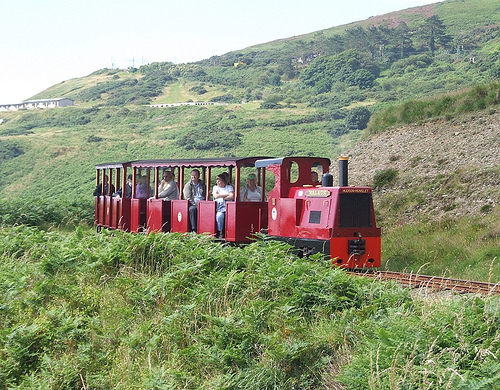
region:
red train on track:
[89, 136, 390, 262]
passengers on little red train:
[87, 144, 373, 271]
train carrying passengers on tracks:
[75, 147, 384, 265]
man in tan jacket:
[177, 167, 202, 213]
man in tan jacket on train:
[184, 170, 206, 205]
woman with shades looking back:
[209, 173, 233, 220]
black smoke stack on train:
[329, 156, 353, 181]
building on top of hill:
[2, 96, 72, 116]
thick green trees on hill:
[256, 17, 498, 124]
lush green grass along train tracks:
[11, 226, 480, 388]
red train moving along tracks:
[85, 154, 398, 286]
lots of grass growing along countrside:
[59, 275, 306, 382]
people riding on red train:
[83, 149, 394, 265]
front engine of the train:
[253, 154, 390, 276]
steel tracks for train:
[365, 258, 490, 313]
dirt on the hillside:
[377, 111, 481, 201]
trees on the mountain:
[263, 38, 418, 98]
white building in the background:
[0, 82, 83, 114]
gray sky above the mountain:
[12, 3, 184, 67]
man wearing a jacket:
[178, 165, 208, 207]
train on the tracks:
[84, 129, 376, 298]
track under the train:
[404, 260, 446, 302]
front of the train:
[325, 180, 404, 253]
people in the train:
[131, 158, 245, 216]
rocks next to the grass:
[447, 125, 478, 155]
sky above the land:
[60, 11, 112, 61]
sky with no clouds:
[93, 16, 120, 36]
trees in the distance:
[315, 43, 370, 98]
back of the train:
[79, 148, 129, 208]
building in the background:
[21, 84, 82, 156]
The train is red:
[47, 142, 384, 268]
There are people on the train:
[78, 153, 279, 225]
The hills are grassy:
[1, 0, 429, 371]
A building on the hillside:
[3, 88, 74, 125]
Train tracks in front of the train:
[347, 261, 487, 299]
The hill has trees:
[110, 22, 407, 147]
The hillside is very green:
[22, 248, 345, 372]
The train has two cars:
[85, 156, 282, 251]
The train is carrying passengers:
[82, 146, 287, 250]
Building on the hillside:
[140, 96, 225, 121]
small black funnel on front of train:
[330, 150, 364, 192]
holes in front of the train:
[367, 253, 381, 265]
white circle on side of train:
[266, 206, 288, 221]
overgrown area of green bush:
[96, 226, 277, 341]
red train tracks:
[390, 253, 492, 303]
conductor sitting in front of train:
[303, 155, 326, 185]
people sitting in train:
[180, 163, 262, 224]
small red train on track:
[86, 143, 405, 267]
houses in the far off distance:
[21, 97, 88, 122]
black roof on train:
[134, 145, 255, 172]